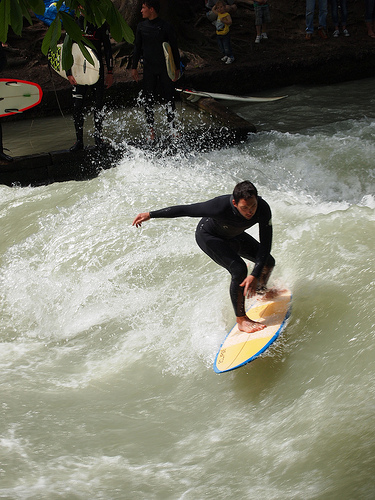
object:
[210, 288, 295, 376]
board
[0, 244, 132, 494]
water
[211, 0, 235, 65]
kid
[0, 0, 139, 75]
tree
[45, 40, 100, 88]
surfboard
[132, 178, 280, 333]
man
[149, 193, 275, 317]
wet suit